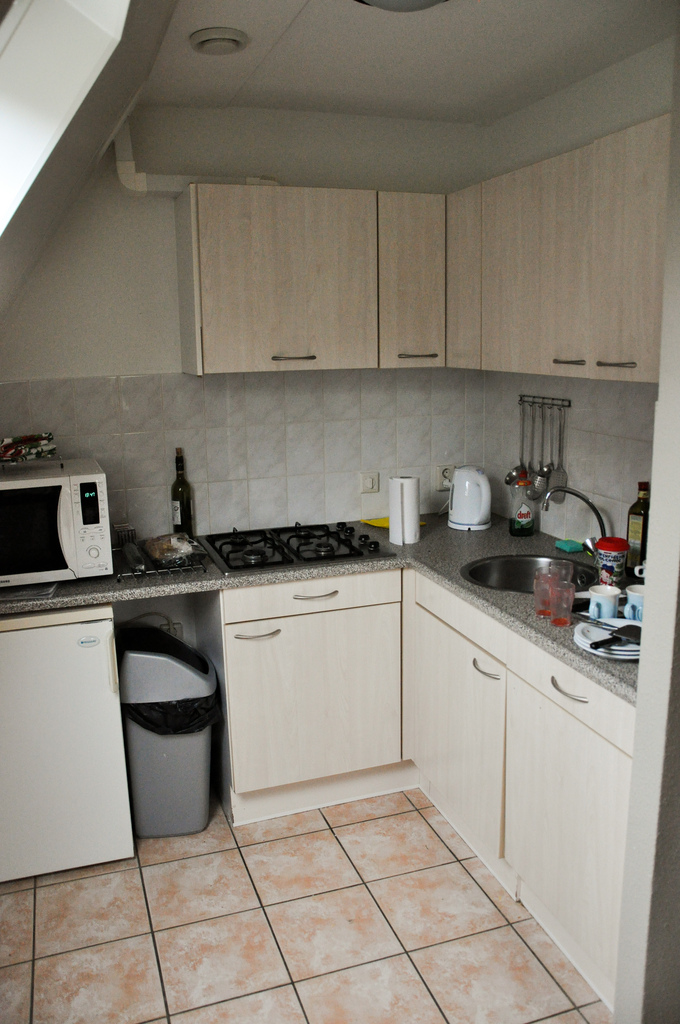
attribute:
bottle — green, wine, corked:
[170, 446, 194, 539]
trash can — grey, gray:
[115, 618, 222, 839]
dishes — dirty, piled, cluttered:
[538, 537, 644, 667]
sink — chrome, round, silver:
[464, 552, 598, 593]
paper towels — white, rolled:
[388, 475, 419, 545]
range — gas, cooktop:
[205, 518, 382, 574]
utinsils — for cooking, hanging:
[502, 387, 571, 507]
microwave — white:
[1, 457, 115, 588]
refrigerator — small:
[1, 602, 142, 884]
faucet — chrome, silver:
[536, 486, 609, 542]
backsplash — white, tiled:
[0, 378, 659, 553]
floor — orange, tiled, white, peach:
[2, 789, 613, 1021]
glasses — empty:
[532, 559, 577, 627]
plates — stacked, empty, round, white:
[571, 614, 641, 663]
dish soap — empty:
[508, 475, 540, 534]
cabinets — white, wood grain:
[166, 107, 676, 377]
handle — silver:
[294, 586, 345, 607]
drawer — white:
[225, 569, 405, 627]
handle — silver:
[543, 669, 587, 708]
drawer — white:
[407, 569, 638, 761]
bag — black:
[129, 675, 219, 734]